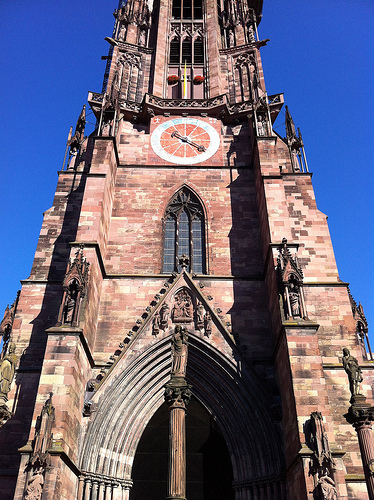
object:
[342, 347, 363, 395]
statue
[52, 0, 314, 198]
pillar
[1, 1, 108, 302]
blue sky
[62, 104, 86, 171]
spires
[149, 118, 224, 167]
square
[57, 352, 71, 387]
brick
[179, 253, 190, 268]
cross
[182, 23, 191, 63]
window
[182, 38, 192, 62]
grill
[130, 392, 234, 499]
arched doorway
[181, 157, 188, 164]
number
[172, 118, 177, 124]
number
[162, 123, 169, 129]
number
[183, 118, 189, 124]
number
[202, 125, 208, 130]
number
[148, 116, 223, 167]
clock face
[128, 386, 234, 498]
entrance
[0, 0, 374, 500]
church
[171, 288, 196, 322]
panel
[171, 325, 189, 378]
woman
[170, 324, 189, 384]
statue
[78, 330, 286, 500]
arch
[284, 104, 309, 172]
decorative spires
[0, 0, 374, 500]
building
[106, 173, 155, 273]
bricks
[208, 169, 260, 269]
bricks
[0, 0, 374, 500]
tower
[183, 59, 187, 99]
needle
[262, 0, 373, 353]
sky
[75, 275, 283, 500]
doorway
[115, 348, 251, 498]
no people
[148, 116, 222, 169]
clock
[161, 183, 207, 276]
window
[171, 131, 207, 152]
needle